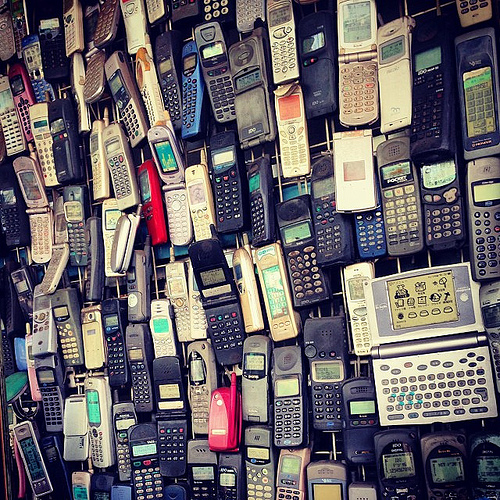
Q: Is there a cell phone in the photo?
A: Yes, there is a cell phone.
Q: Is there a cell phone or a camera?
A: Yes, there is a cell phone.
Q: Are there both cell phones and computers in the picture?
A: No, there is a cell phone but no computers.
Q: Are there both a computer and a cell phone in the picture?
A: No, there is a cell phone but no computers.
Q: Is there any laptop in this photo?
A: No, there are no laptops.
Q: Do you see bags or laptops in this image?
A: No, there are no laptops or bags.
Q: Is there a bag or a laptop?
A: No, there are no laptops or bags.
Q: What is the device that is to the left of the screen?
A: The device is a cell phone.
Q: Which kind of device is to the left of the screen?
A: The device is a cell phone.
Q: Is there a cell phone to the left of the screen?
A: Yes, there is a cell phone to the left of the screen.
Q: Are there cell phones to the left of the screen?
A: Yes, there is a cell phone to the left of the screen.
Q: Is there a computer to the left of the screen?
A: No, there is a cell phone to the left of the screen.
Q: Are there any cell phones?
A: Yes, there is a cell phone.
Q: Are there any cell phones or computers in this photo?
A: Yes, there is a cell phone.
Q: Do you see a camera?
A: No, there are no cameras.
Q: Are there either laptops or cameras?
A: No, there are no cameras or laptops.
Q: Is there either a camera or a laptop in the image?
A: No, there are no cameras or laptops.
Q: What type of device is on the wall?
A: The device is a cell phone.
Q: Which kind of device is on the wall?
A: The device is a cell phone.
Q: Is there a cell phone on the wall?
A: Yes, there is a cell phone on the wall.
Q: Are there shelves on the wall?
A: No, there is a cell phone on the wall.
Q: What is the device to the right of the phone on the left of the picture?
A: The device is a cell phone.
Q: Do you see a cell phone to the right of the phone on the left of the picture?
A: Yes, there is a cell phone to the right of the telephone.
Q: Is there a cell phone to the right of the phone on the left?
A: Yes, there is a cell phone to the right of the telephone.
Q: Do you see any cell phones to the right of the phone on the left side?
A: Yes, there is a cell phone to the right of the telephone.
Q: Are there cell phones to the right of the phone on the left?
A: Yes, there is a cell phone to the right of the telephone.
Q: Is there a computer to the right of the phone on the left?
A: No, there is a cell phone to the right of the phone.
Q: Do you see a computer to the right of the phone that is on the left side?
A: No, there is a cell phone to the right of the phone.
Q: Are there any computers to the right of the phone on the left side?
A: No, there is a cell phone to the right of the phone.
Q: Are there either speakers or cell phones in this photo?
A: Yes, there is a cell phone.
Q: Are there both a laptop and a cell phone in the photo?
A: No, there is a cell phone but no laptops.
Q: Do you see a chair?
A: No, there are no chairs.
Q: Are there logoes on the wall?
A: No, there is a cell phone on the wall.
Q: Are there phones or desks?
A: Yes, there is a phone.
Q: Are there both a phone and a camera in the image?
A: No, there is a phone but no cameras.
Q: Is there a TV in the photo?
A: No, there are no televisions.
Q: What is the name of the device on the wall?
A: The device is a phone.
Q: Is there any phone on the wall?
A: Yes, there is a phone on the wall.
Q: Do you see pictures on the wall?
A: No, there is a phone on the wall.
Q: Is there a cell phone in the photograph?
A: Yes, there is a cell phone.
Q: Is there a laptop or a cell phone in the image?
A: Yes, there is a cell phone.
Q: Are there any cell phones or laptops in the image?
A: Yes, there is a cell phone.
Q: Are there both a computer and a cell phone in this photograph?
A: No, there is a cell phone but no computers.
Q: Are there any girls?
A: No, there are no girls.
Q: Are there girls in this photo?
A: No, there are no girls.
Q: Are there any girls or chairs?
A: No, there are no girls or chairs.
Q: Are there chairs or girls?
A: No, there are no girls or chairs.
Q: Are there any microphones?
A: No, there are no microphones.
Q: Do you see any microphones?
A: No, there are no microphones.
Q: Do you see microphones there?
A: No, there are no microphones.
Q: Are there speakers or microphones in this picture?
A: No, there are no microphones or speakers.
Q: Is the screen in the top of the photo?
A: Yes, the screen is in the top of the image.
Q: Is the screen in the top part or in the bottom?
A: The screen is in the top of the image.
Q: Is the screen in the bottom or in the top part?
A: The screen is in the top of the image.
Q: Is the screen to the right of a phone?
A: Yes, the screen is to the right of a phone.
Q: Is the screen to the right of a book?
A: No, the screen is to the right of a phone.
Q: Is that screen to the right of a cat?
A: No, the screen is to the right of the cellphone.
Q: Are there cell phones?
A: Yes, there is a cell phone.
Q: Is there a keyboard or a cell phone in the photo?
A: Yes, there is a cell phone.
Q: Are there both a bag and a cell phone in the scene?
A: No, there is a cell phone but no bags.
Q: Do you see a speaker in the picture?
A: No, there are no speakers.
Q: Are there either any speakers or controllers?
A: No, there are no speakers or controllers.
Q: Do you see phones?
A: Yes, there is a phone.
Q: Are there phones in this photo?
A: Yes, there is a phone.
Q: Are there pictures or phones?
A: Yes, there is a phone.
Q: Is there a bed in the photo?
A: No, there are no beds.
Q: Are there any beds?
A: No, there are no beds.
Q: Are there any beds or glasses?
A: No, there are no beds or glasses.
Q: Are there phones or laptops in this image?
A: Yes, there is a phone.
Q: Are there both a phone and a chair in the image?
A: No, there is a phone but no chairs.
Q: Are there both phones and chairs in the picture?
A: No, there is a phone but no chairs.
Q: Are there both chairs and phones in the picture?
A: No, there is a phone but no chairs.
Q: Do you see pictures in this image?
A: No, there are no pictures.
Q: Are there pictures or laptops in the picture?
A: No, there are no pictures or laptops.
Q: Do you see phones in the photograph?
A: Yes, there is a phone.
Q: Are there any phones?
A: Yes, there is a phone.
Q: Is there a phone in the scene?
A: Yes, there is a phone.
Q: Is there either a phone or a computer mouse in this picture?
A: Yes, there is a phone.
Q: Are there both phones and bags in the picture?
A: No, there is a phone but no bags.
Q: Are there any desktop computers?
A: No, there are no desktop computers.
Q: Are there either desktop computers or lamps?
A: No, there are no desktop computers or lamps.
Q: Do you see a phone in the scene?
A: Yes, there is a phone.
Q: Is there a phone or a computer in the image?
A: Yes, there is a phone.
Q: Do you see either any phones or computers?
A: Yes, there is a phone.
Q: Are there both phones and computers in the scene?
A: No, there is a phone but no computers.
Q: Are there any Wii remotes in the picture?
A: No, there are no Wii remotes.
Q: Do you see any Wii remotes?
A: No, there are no Wii remotes.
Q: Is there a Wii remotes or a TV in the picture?
A: No, there are no Wii controllers or televisions.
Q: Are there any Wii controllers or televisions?
A: No, there are no Wii controllers or televisions.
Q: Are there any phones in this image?
A: Yes, there is a phone.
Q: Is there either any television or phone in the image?
A: Yes, there is a phone.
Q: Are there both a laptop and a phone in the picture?
A: No, there is a phone but no laptops.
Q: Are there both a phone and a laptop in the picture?
A: No, there is a phone but no laptops.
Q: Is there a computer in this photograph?
A: No, there are no computers.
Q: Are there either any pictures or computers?
A: No, there are no computers or pictures.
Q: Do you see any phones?
A: Yes, there is a phone.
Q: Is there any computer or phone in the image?
A: Yes, there is a phone.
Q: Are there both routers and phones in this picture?
A: No, there is a phone but no routers.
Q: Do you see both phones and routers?
A: No, there is a phone but no routers.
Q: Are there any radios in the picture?
A: No, there are no radios.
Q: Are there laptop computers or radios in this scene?
A: No, there are no radios or laptop computers.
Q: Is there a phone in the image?
A: Yes, there is a phone.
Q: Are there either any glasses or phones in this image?
A: Yes, there is a phone.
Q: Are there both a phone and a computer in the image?
A: No, there is a phone but no computers.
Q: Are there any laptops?
A: No, there are no laptops.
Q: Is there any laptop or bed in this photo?
A: No, there are no laptops or beds.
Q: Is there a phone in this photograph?
A: Yes, there is a phone.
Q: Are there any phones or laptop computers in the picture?
A: Yes, there is a phone.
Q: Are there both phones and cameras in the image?
A: No, there is a phone but no cameras.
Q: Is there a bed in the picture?
A: No, there are no beds.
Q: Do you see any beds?
A: No, there are no beds.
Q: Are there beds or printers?
A: No, there are no beds or printers.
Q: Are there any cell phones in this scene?
A: Yes, there is a cell phone.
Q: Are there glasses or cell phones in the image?
A: Yes, there is a cell phone.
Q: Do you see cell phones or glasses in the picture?
A: Yes, there is a cell phone.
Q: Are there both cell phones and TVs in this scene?
A: No, there is a cell phone but no televisions.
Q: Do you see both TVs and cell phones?
A: No, there is a cell phone but no televisions.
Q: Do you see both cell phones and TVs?
A: No, there is a cell phone but no televisions.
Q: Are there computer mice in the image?
A: No, there are no computer mice.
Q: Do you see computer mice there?
A: No, there are no computer mice.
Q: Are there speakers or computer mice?
A: No, there are no computer mice or speakers.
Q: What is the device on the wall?
A: The device is a cell phone.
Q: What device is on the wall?
A: The device is a cell phone.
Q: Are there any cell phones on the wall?
A: Yes, there is a cell phone on the wall.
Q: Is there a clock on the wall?
A: No, there is a cell phone on the wall.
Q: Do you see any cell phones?
A: Yes, there is a cell phone.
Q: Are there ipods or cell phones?
A: Yes, there is a cell phone.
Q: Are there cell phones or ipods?
A: Yes, there is a cell phone.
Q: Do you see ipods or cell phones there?
A: Yes, there is a cell phone.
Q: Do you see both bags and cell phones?
A: No, there is a cell phone but no bags.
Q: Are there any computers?
A: No, there are no computers.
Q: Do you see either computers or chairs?
A: No, there are no computers or chairs.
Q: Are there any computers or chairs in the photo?
A: No, there are no computers or chairs.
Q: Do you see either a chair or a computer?
A: No, there are no computers or chairs.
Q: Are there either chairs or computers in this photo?
A: No, there are no computers or chairs.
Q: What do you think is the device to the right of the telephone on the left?
A: The device is a cell phone.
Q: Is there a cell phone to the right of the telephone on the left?
A: Yes, there is a cell phone to the right of the phone.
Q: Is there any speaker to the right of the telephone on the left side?
A: No, there is a cell phone to the right of the phone.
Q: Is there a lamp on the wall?
A: No, there is a cell phone on the wall.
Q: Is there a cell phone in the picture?
A: Yes, there is a cell phone.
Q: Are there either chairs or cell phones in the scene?
A: Yes, there is a cell phone.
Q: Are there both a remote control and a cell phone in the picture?
A: No, there is a cell phone but no remote controls.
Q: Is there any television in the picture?
A: No, there are no televisions.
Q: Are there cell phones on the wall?
A: Yes, there is a cell phone on the wall.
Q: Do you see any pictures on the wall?
A: No, there is a cell phone on the wall.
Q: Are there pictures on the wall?
A: No, there is a cell phone on the wall.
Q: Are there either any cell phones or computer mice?
A: Yes, there is a cell phone.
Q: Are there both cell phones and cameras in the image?
A: No, there is a cell phone but no cameras.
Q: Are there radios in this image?
A: No, there are no radios.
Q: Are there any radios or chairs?
A: No, there are no radios or chairs.